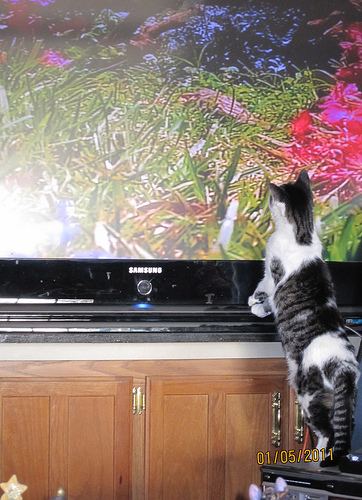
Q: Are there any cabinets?
A: Yes, there is a cabinet.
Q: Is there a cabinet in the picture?
A: Yes, there is a cabinet.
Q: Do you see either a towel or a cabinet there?
A: Yes, there is a cabinet.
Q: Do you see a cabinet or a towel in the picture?
A: Yes, there is a cabinet.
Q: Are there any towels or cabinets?
A: Yes, there is a cabinet.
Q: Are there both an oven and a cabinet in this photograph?
A: No, there is a cabinet but no ovens.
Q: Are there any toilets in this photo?
A: No, there are no toilets.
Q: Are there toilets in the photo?
A: No, there are no toilets.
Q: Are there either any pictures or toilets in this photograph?
A: No, there are no toilets or pictures.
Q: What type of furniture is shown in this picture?
A: The furniture is a cabinet.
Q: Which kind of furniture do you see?
A: The furniture is a cabinet.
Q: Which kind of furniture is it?
A: The piece of furniture is a cabinet.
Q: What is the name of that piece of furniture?
A: This is a cabinet.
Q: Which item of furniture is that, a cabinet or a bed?
A: This is a cabinet.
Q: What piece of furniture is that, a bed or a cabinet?
A: This is a cabinet.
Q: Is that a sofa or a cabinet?
A: That is a cabinet.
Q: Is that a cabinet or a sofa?
A: That is a cabinet.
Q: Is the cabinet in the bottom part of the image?
A: Yes, the cabinet is in the bottom of the image.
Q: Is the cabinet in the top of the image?
A: No, the cabinet is in the bottom of the image.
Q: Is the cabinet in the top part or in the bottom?
A: The cabinet is in the bottom of the image.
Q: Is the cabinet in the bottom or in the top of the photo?
A: The cabinet is in the bottom of the image.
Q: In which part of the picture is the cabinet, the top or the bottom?
A: The cabinet is in the bottom of the image.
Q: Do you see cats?
A: Yes, there is a cat.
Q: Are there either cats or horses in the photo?
A: Yes, there is a cat.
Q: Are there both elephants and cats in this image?
A: No, there is a cat but no elephants.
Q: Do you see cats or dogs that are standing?
A: Yes, the cat is standing.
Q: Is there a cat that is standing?
A: Yes, there is a cat that is standing.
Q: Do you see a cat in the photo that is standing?
A: Yes, there is a cat that is standing.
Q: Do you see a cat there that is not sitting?
A: Yes, there is a cat that is standing .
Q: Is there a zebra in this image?
A: No, there are no zebras.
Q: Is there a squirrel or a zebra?
A: No, there are no zebras or squirrels.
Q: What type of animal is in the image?
A: The animal is a cat.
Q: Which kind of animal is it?
A: The animal is a cat.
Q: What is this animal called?
A: This is a cat.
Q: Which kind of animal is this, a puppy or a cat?
A: This is a cat.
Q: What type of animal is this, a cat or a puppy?
A: This is a cat.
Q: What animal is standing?
A: The animal is a cat.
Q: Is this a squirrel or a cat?
A: This is a cat.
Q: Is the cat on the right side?
A: Yes, the cat is on the right of the image.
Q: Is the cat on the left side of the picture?
A: No, the cat is on the right of the image.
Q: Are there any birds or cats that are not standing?
A: No, there is a cat but it is standing.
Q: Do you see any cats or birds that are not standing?
A: No, there is a cat but it is standing.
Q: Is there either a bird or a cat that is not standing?
A: No, there is a cat but it is standing.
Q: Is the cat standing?
A: Yes, the cat is standing.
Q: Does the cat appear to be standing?
A: Yes, the cat is standing.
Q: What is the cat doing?
A: The cat is standing.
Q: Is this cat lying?
A: No, the cat is standing.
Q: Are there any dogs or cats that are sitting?
A: No, there is a cat but it is standing.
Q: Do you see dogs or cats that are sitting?
A: No, there is a cat but it is standing.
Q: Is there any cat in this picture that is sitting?
A: No, there is a cat but it is standing.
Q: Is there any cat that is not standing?
A: No, there is a cat but it is standing.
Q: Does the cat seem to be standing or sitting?
A: The cat is standing.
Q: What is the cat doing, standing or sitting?
A: The cat is standing.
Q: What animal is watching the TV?
A: The cat is watching the TV.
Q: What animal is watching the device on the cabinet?
A: The cat is watching the TV.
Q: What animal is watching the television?
A: The cat is watching the TV.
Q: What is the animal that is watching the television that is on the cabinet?
A: The animal is a cat.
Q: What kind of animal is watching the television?
A: The animal is a cat.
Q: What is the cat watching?
A: The cat is watching the television.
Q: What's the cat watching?
A: The cat is watching the television.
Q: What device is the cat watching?
A: The cat is watching the TV.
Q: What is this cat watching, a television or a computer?
A: The cat is watching a television.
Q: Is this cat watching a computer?
A: No, the cat is watching a television.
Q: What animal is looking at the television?
A: The cat is looking at the television.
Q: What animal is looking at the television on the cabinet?
A: The animal is a cat.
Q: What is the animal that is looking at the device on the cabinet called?
A: The animal is a cat.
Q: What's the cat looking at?
A: The cat is looking at the television.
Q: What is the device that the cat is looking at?
A: The device is a television.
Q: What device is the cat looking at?
A: The cat is looking at the television.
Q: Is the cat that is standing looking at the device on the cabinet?
A: Yes, the cat is looking at the TV.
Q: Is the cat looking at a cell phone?
A: No, the cat is looking at the TV.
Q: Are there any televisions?
A: Yes, there is a television.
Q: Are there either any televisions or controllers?
A: Yes, there is a television.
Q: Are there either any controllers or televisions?
A: Yes, there is a television.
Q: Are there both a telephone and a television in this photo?
A: No, there is a television but no phones.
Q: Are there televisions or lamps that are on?
A: Yes, the television is on.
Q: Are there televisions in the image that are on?
A: Yes, there is a television that is on.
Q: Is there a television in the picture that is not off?
A: Yes, there is a television that is on.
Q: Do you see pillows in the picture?
A: No, there are no pillows.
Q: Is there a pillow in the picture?
A: No, there are no pillows.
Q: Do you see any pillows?
A: No, there are no pillows.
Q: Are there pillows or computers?
A: No, there are no pillows or computers.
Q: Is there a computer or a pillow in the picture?
A: No, there are no pillows or computers.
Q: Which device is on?
A: The device is a television.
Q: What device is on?
A: The device is a television.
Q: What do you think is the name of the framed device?
A: The device is a television.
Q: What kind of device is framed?
A: The device is a television.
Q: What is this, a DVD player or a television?
A: This is a television.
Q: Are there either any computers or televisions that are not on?
A: No, there is a television but it is on.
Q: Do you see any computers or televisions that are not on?
A: No, there is a television but it is on.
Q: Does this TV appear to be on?
A: Yes, the TV is on.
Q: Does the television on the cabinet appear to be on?
A: Yes, the television is on.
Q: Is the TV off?
A: No, the TV is on.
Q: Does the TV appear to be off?
A: No, the TV is on.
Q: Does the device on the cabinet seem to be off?
A: No, the TV is on.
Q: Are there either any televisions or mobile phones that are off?
A: No, there is a television but it is on.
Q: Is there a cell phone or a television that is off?
A: No, there is a television but it is on.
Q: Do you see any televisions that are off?
A: No, there is a television but it is on.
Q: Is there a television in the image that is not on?
A: No, there is a television but it is on.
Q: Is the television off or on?
A: The television is on.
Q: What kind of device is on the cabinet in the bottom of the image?
A: The device is a television.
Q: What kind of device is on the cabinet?
A: The device is a television.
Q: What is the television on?
A: The television is on the cabinet.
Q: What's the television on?
A: The television is on the cabinet.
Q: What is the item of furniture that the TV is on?
A: The piece of furniture is a cabinet.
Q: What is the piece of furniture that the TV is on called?
A: The piece of furniture is a cabinet.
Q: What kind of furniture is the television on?
A: The TV is on the cabinet.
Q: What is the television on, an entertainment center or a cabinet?
A: The television is on a cabinet.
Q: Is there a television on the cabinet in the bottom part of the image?
A: Yes, there is a television on the cabinet.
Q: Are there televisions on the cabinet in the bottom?
A: Yes, there is a television on the cabinet.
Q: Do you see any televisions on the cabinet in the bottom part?
A: Yes, there is a television on the cabinet.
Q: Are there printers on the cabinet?
A: No, there is a television on the cabinet.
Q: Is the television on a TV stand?
A: No, the television is on a cabinet.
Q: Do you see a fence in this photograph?
A: No, there are no fences.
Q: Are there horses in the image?
A: No, there are no horses.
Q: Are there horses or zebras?
A: No, there are no horses or zebras.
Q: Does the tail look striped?
A: Yes, the tail is striped.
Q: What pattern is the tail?
A: The tail is striped.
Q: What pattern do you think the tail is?
A: The tail is striped.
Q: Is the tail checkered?
A: No, the tail is striped.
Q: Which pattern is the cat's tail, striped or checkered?
A: The tail is striped.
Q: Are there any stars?
A: Yes, there is a star.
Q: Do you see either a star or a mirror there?
A: Yes, there is a star.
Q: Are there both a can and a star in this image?
A: No, there is a star but no cans.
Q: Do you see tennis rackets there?
A: No, there are no tennis rackets.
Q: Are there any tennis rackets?
A: No, there are no tennis rackets.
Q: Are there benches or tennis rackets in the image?
A: No, there are no tennis rackets or benches.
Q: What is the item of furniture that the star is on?
A: The piece of furniture is a cabinet.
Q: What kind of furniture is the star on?
A: The star is on the cabinet.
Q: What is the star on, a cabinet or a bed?
A: The star is on a cabinet.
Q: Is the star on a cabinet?
A: Yes, the star is on a cabinet.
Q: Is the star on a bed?
A: No, the star is on a cabinet.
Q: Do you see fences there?
A: No, there are no fences.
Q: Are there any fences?
A: No, there are no fences.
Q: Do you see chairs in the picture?
A: No, there are no chairs.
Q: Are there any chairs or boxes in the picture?
A: No, there are no chairs or boxes.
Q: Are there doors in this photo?
A: Yes, there is a door.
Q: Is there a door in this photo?
A: Yes, there is a door.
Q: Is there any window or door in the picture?
A: Yes, there is a door.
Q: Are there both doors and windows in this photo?
A: No, there is a door but no windows.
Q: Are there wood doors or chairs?
A: Yes, there is a wood door.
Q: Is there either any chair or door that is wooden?
A: Yes, the door is wooden.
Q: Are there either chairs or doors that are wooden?
A: Yes, the door is wooden.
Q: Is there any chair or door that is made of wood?
A: Yes, the door is made of wood.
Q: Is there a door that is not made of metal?
A: Yes, there is a door that is made of wood.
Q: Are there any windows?
A: No, there are no windows.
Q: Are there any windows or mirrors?
A: No, there are no windows or mirrors.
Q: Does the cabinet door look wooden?
A: Yes, the door is wooden.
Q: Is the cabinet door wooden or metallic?
A: The door is wooden.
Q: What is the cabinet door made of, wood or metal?
A: The door is made of wood.